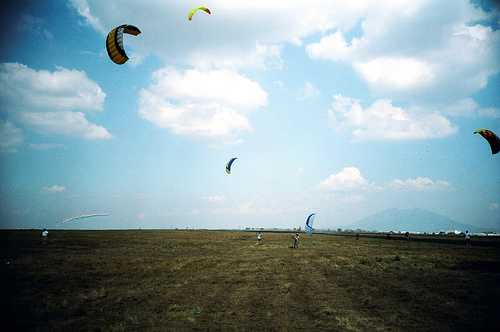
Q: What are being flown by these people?
A: Kites.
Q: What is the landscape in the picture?
A: Open field.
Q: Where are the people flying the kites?
A: Grass field.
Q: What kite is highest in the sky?
A: Yello, green and red one.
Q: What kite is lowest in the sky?
A: All blue one.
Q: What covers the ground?
A: Grass.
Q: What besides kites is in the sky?
A: Clouds.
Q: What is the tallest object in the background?
A: Mountain.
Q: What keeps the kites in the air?
A: Wind.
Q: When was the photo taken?
A: Daylight hours.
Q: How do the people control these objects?
A: Strings.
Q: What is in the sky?
A: Kites.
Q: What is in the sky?
A: Kites.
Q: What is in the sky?
A: Kites.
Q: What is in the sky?
A: Clouds.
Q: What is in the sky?
A: Clouds.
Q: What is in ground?
A: Grass.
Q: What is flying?
A: Kites.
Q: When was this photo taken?
A: Daytime.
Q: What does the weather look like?
A: Cloudy.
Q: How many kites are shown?
A: 5.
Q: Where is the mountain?
A: Right.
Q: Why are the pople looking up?
A: Flying kites.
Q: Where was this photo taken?
A: At an open field.